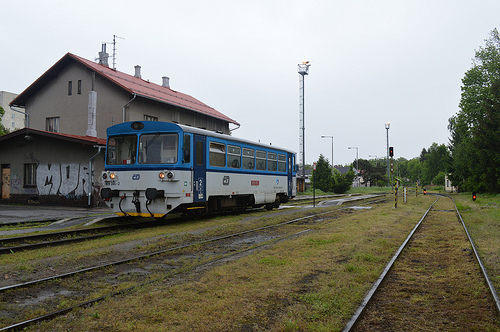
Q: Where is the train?
A: On the tracks.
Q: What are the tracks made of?
A: Metal.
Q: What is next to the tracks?
A: Grass.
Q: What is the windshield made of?
A: Glass.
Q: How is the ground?
A: Wet.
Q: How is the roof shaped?
A: Triangle.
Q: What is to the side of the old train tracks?
A: Trees.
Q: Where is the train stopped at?
A: Train station.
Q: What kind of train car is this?
A: Passenger.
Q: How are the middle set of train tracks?
A: Buried in grass.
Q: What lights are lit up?
A: Red stop lights.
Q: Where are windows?
A: On train and building.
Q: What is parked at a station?
A: One passenger train car.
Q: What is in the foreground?
A: Train tracks.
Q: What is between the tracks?
A: Patchy green grass.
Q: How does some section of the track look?
A: Section looks wet.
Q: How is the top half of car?
A: It is blue in color.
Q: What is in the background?
A: Green trees.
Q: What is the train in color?
A: White and blue.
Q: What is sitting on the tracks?
A: The train.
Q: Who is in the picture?
A: There are no people in the picture.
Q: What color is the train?
A: Blue and white.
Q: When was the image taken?
A: During the day.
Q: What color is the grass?
A: Green.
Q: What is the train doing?
A: The train is parked.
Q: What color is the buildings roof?
A: Red.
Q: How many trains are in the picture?
A: One.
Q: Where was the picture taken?
A: At a train station.